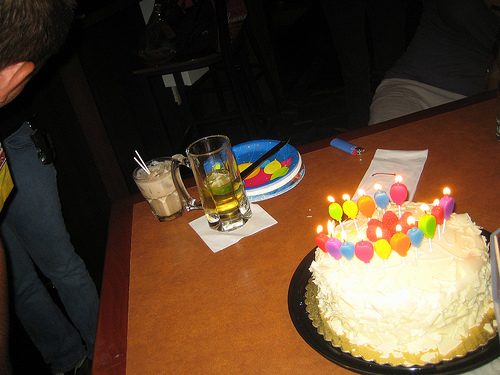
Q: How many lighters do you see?
A: 1.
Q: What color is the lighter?
A: Blue.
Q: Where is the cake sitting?
A: On the table.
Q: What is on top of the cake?
A: Candles.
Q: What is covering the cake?
A: Frosting.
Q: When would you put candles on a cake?
A: At a birthday party.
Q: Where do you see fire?
A: On the candles.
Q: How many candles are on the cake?
A: 15.